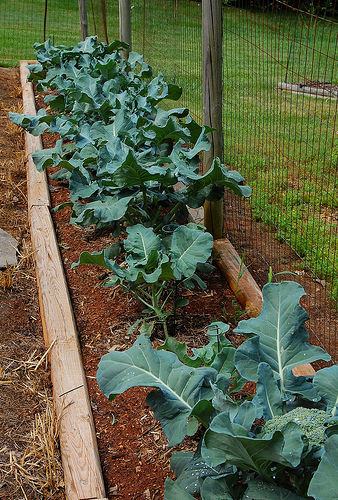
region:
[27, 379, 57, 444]
Big green flowers next to a plant.Big green flowers next to a plant.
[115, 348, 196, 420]
green leaf of collard greens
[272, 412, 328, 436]
flower blossom in middle of bunch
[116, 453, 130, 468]
brown and orange soil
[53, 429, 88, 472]
wooden border nailed in ground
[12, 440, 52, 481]
dry grass by border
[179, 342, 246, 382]
small green bunch of greens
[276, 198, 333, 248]
wire connected to wooden board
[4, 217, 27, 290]
flat rock by garden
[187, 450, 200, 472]
drops of moisture on leaf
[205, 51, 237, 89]
faded wooden support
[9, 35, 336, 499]
The plants are deep green.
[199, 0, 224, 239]
The wooden post is gray.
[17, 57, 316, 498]
The border is made of wood.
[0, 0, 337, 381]
The fence is made of crossed wire.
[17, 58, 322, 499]
The wooden border is unpainted.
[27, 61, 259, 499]
The dirt is reddish-brown.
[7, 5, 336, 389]
The fence wires cross horizontally and vertically.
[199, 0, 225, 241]
The fence post is split in some spots.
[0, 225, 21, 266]
A stone is partially visible.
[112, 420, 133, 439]
part of a ground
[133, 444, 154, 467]
part of a ground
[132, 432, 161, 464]
part of a ground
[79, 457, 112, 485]
edge of a wood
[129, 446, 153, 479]
part of a ground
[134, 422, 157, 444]
part of a ground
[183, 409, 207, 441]
aprt of a leaf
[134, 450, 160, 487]
part of a ground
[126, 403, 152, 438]
part of a ground